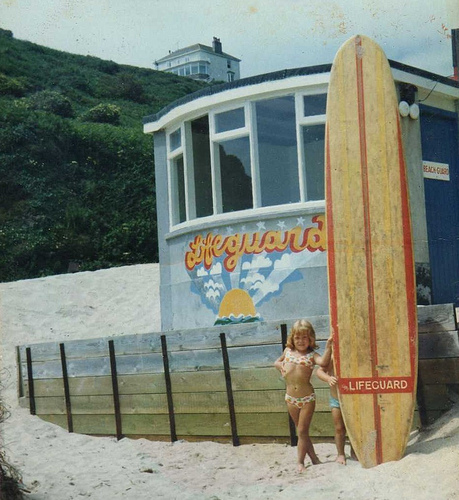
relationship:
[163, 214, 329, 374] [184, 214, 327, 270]
sign indicating lifeguard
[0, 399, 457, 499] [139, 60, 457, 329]
beach and house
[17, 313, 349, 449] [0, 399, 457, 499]
fence between beach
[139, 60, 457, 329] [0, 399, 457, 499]
house on beach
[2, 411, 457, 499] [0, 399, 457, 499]
sand alongside beach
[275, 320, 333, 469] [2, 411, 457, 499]
girl standing in sand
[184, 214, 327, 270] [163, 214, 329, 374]
lifeguard on sign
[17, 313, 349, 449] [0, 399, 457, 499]
fence on beach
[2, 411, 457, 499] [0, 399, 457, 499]
sand on beach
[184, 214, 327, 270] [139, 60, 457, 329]
lifeguard on house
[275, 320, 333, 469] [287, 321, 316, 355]
girl with hair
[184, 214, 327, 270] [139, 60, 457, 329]
lifeguard on a house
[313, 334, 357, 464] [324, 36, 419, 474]
boy behind board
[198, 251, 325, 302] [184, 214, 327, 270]
clouds under lifeguard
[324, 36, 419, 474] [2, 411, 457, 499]
board in sand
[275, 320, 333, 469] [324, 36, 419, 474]
girl beside board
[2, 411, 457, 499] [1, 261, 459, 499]
sand on ground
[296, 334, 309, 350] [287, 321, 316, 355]
face with hair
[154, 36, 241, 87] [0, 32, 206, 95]
house on hill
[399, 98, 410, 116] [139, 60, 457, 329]
light on house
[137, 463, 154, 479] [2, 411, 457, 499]
grass in sand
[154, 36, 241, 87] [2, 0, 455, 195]
house in background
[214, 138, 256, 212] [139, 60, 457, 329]
window of house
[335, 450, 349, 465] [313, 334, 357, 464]
foot of a boy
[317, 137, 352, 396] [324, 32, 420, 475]
stripe on board